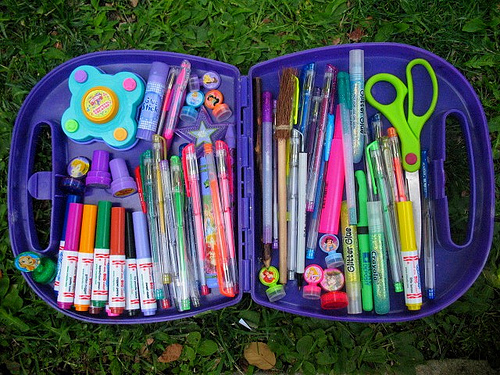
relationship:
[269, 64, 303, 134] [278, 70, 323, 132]
bristles on paintbrush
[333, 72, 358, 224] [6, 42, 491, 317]
pen in art box